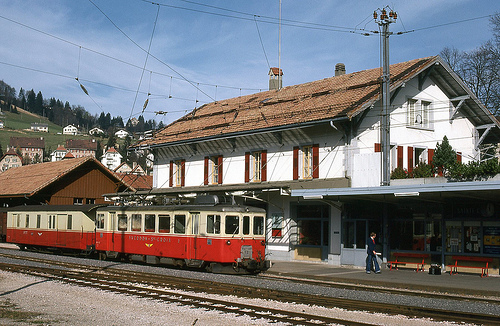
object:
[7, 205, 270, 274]
tram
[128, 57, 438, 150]
roof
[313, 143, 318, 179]
shutter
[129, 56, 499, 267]
building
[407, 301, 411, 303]
gravel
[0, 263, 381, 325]
track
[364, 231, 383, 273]
person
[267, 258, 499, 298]
platform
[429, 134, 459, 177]
plant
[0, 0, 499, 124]
sky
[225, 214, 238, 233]
windshield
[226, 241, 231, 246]
light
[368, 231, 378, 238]
head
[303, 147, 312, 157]
window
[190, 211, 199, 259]
door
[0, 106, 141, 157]
grass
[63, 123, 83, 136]
house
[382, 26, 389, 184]
pole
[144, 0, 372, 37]
wire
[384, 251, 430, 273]
bench